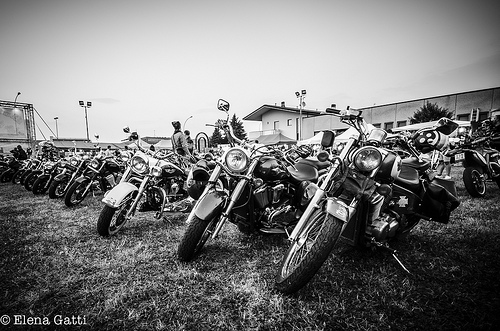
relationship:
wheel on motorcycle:
[272, 204, 344, 292] [275, 107, 459, 290]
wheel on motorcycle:
[181, 193, 227, 267] [174, 98, 340, 265]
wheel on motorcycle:
[93, 184, 139, 238] [93, 125, 204, 235]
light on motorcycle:
[351, 146, 382, 171] [275, 107, 459, 290]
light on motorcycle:
[224, 147, 248, 175] [174, 98, 340, 265]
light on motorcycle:
[127, 153, 152, 178] [93, 125, 204, 235]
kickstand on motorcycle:
[388, 252, 417, 275] [275, 107, 459, 290]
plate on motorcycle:
[454, 152, 467, 160] [454, 141, 499, 195]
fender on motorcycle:
[324, 194, 351, 229] [275, 107, 459, 290]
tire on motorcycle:
[272, 204, 344, 292] [275, 107, 459, 290]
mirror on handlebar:
[217, 97, 231, 114] [218, 99, 297, 156]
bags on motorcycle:
[424, 175, 457, 225] [275, 107, 459, 290]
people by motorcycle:
[165, 121, 196, 165] [93, 125, 204, 235]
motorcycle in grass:
[275, 107, 459, 290] [0, 124, 496, 328]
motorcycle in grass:
[174, 98, 340, 265] [0, 124, 496, 328]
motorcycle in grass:
[93, 125, 204, 235] [0, 124, 496, 328]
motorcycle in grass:
[454, 141, 499, 195] [0, 124, 496, 328]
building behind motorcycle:
[238, 83, 497, 136] [454, 141, 499, 195]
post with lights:
[295, 89, 308, 144] [293, 88, 309, 98]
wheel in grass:
[272, 204, 344, 292] [0, 124, 496, 328]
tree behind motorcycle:
[211, 115, 248, 151] [93, 125, 204, 235]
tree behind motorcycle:
[408, 102, 457, 124] [454, 141, 499, 195]